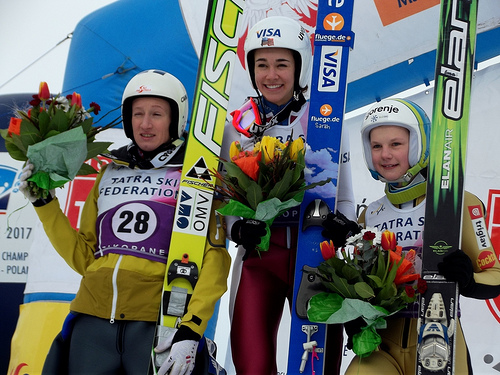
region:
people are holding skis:
[25, 8, 475, 354]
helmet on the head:
[119, 71, 180, 98]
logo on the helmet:
[238, 18, 290, 50]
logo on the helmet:
[352, 97, 422, 127]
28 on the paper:
[97, 182, 162, 247]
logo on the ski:
[317, 31, 339, 99]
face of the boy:
[364, 124, 406, 179]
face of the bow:
[127, 95, 179, 144]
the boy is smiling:
[247, 45, 294, 102]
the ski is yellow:
[180, 240, 205, 255]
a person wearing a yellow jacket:
[91, 67, 181, 357]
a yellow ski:
[174, 8, 224, 370]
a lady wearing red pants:
[231, 21, 321, 363]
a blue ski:
[303, 23, 344, 362]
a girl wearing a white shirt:
[358, 110, 485, 374]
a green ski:
[418, 23, 480, 371]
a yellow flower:
[253, 133, 276, 155]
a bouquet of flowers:
[308, 225, 430, 344]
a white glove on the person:
[152, 332, 212, 374]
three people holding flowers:
[29, 35, 481, 322]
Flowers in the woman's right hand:
[0, 90, 110, 203]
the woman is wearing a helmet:
[362, 102, 429, 182]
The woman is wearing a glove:
[155, 324, 201, 374]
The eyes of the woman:
[132, 108, 162, 118]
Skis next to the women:
[146, 1, 478, 374]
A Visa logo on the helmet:
[256, 27, 281, 37]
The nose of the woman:
[266, 64, 278, 80]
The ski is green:
[416, 2, 478, 374]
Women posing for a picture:
[17, 15, 497, 373]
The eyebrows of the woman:
[253, 55, 290, 62]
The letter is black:
[110, 171, 119, 188]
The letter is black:
[113, 175, 126, 187]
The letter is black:
[121, 170, 133, 186]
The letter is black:
[132, 170, 142, 184]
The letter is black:
[140, 169, 154, 186]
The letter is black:
[154, 172, 164, 187]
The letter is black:
[160, 172, 174, 188]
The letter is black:
[171, 175, 183, 190]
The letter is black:
[103, 183, 114, 198]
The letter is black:
[108, 182, 121, 197]